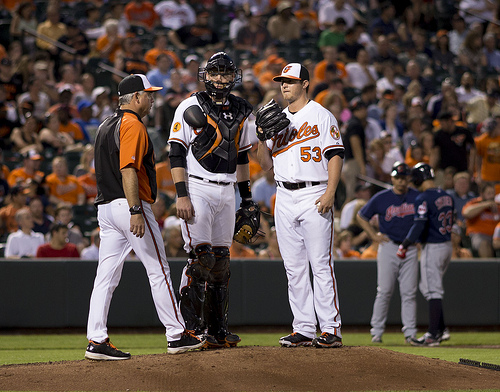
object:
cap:
[272, 62, 310, 82]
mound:
[0, 346, 499, 392]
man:
[85, 73, 207, 361]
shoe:
[84, 337, 131, 361]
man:
[255, 62, 345, 348]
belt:
[275, 179, 328, 190]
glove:
[255, 99, 291, 142]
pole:
[21, 27, 393, 189]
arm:
[119, 121, 146, 238]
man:
[356, 161, 422, 347]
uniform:
[358, 186, 419, 337]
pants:
[369, 242, 420, 338]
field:
[0, 329, 498, 389]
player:
[396, 161, 458, 347]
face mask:
[197, 52, 243, 99]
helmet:
[410, 162, 435, 188]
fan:
[4, 207, 44, 260]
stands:
[0, 1, 499, 260]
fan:
[9, 114, 43, 154]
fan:
[461, 181, 499, 259]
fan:
[341, 97, 369, 211]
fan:
[37, 222, 80, 258]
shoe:
[166, 332, 207, 354]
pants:
[274, 180, 342, 340]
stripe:
[329, 208, 341, 336]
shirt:
[265, 99, 346, 183]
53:
[300, 146, 322, 163]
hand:
[314, 193, 335, 215]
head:
[272, 63, 310, 103]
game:
[0, 51, 500, 392]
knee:
[197, 250, 216, 271]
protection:
[179, 242, 216, 334]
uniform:
[396, 187, 456, 346]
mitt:
[233, 200, 270, 246]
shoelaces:
[106, 341, 119, 352]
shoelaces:
[185, 329, 202, 342]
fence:
[0, 259, 499, 331]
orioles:
[267, 121, 321, 162]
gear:
[167, 51, 261, 348]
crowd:
[0, 0, 499, 258]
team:
[84, 51, 345, 361]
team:
[356, 161, 455, 347]